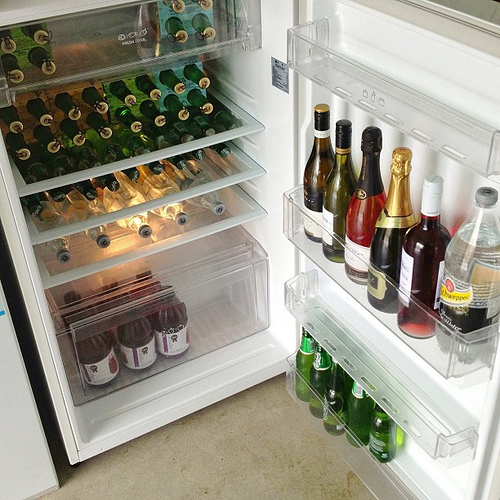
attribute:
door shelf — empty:
[285, 17, 499, 179]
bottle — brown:
[302, 103, 336, 243]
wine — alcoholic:
[398, 217, 451, 340]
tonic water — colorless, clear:
[436, 223, 499, 363]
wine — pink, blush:
[343, 188, 388, 279]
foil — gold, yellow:
[384, 147, 415, 218]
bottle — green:
[345, 380, 374, 447]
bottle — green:
[308, 343, 333, 420]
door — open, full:
[295, 1, 499, 499]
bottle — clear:
[434, 184, 499, 364]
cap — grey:
[474, 186, 499, 204]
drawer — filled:
[42, 225, 271, 407]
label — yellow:
[438, 278, 474, 307]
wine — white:
[322, 164, 358, 262]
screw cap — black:
[334, 120, 352, 136]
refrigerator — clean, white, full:
[4, 1, 496, 491]